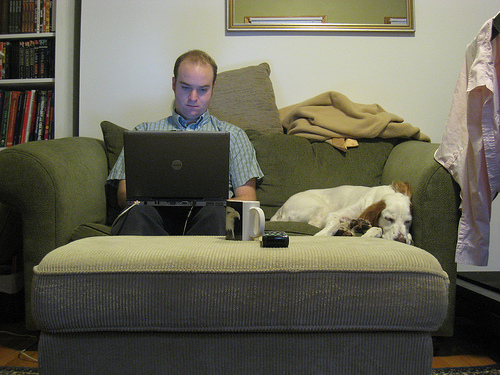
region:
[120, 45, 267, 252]
Man sitting on a couch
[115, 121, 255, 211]
Man on his laptop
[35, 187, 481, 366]
Footstool in front of couch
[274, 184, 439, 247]
Dog laying on the couch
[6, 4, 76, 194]
White bookcase with books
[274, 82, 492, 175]
Blanket on top of couch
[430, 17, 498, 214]
Shirt hanging on hanger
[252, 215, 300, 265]
Remote on a footstool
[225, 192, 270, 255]
Coffee cup on footstool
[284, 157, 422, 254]
Dog has floppy brown ears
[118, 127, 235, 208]
a gray laptop on a man's lap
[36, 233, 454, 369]
a gray ottoman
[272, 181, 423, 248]
a dog sleeping on a couch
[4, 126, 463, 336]
a green couch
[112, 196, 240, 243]
gray pants on a man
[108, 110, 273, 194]
a plaid shirt on a man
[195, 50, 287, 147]
a pillow on the back of the couch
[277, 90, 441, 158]
a light brown blanket on the top of a couch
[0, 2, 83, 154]
a bookshelf full of books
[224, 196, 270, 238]
a coffee mug on an ottoman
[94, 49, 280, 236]
a man sitting on a couch working on laptop computer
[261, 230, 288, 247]
a tv remote control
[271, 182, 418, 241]
a large do laying on the couch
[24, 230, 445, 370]
an ottoman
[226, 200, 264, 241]
a coffee mug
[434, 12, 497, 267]
a man's shirt hanging on a hanger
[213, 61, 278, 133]
a throw pillow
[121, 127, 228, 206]
a laptop computer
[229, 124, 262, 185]
the sleeve of a man's plaid shirt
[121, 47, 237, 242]
man looking at laptop computer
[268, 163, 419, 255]
white dog on small couch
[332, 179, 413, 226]
white dog has brown ears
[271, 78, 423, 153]
blanket on back of couch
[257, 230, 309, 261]
remote is on footstool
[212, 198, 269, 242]
coffee mug is beside remote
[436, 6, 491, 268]
short pale pink coat on a hanger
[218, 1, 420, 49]
mirror above small couch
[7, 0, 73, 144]
books on white bookshelves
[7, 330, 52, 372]
hardwood floor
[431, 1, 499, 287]
wrinkled shirt on a hanger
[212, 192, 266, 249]
coffee mug with a picture of an eagle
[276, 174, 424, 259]
dog sleeping on the couch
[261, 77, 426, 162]
crumpled blanket on back of the couch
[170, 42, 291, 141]
brown throw pillow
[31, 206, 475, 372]
green corduroy ottoman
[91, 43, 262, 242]
man using a laptop compter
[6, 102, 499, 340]
green love seat sofa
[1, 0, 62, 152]
shelves filled with books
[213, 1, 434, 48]
mirror hanging on the wall